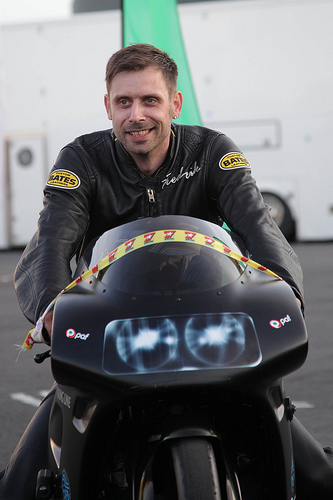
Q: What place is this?
A: It is a road.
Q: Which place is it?
A: It is a road.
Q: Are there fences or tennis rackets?
A: No, there are no fences or tennis rackets.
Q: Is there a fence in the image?
A: No, there are no fences.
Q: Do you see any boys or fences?
A: No, there are no fences or boys.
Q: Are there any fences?
A: No, there are no fences.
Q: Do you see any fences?
A: No, there are no fences.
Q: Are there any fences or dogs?
A: No, there are no fences or dogs.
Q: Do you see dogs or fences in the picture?
A: No, there are no fences or dogs.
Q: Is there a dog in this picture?
A: No, there are no dogs.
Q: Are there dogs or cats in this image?
A: No, there are no dogs or cats.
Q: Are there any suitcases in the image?
A: No, there are no suitcases.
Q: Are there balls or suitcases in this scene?
A: No, there are no suitcases or balls.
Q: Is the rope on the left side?
A: Yes, the rope is on the left of the image.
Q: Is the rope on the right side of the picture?
A: No, the rope is on the left of the image.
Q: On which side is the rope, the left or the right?
A: The rope is on the left of the image.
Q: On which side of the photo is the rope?
A: The rope is on the left of the image.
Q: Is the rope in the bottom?
A: Yes, the rope is in the bottom of the image.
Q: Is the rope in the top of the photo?
A: No, the rope is in the bottom of the image.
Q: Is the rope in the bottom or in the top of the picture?
A: The rope is in the bottom of the image.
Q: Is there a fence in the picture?
A: No, there are no fences.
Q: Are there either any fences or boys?
A: No, there are no fences or boys.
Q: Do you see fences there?
A: No, there are no fences.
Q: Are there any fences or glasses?
A: No, there are no fences or glasses.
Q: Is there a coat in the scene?
A: Yes, there is a coat.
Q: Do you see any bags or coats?
A: Yes, there is a coat.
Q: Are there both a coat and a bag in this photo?
A: No, there is a coat but no bags.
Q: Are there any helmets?
A: No, there are no helmets.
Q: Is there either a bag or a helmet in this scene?
A: No, there are no helmets or bags.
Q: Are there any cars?
A: No, there are no cars.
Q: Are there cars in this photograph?
A: No, there are no cars.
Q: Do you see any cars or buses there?
A: No, there are no cars or buses.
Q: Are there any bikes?
A: Yes, there is a bike.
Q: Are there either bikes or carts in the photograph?
A: Yes, there is a bike.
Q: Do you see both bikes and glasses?
A: No, there is a bike but no glasses.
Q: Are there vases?
A: No, there are no vases.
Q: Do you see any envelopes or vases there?
A: No, there are no vases or envelopes.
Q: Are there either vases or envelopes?
A: No, there are no vases or envelopes.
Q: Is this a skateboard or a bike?
A: This is a bike.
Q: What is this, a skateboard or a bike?
A: This is a bike.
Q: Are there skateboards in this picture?
A: No, there are no skateboards.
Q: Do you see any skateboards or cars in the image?
A: No, there are no skateboards or cars.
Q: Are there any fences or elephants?
A: No, there are no fences or elephants.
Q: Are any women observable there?
A: No, there are no women.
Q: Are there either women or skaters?
A: No, there are no women or skaters.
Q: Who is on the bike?
A: The man is on the bike.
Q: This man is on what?
A: The man is on the bike.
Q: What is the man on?
A: The man is on the bike.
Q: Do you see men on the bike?
A: Yes, there is a man on the bike.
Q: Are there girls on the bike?
A: No, there is a man on the bike.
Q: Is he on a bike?
A: Yes, the man is on a bike.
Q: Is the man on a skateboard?
A: No, the man is on a bike.